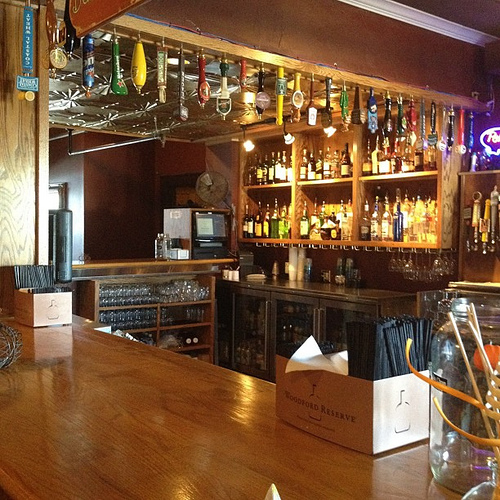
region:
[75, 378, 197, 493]
this is the counter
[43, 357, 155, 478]
the counter is wooden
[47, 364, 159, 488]
the counter is brown in color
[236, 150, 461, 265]
these are some shelves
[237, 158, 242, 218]
the shelves are wooden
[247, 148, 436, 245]
these are some bottles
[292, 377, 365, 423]
this is a box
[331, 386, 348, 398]
the box is brown in color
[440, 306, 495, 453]
this is a jar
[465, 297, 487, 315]
the jar is made of glass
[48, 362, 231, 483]
the table is clean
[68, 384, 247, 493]
the table is wooden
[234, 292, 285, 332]
this is a shelf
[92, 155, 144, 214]
this is the wall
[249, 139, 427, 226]
these are bottles of wine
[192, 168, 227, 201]
this is a fan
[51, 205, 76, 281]
this is a bottle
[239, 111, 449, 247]
Liquor bottles on shelves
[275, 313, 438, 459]
Straws and napkins in a box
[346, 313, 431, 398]
Black plastic stirring straws in a box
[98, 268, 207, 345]
Glasses on shelves under counter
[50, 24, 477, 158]
Key taps hanging from ceiling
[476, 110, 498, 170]
Neon sign on the wall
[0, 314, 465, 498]
Wooden bar top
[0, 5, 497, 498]
An empty bar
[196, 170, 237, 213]
Fan by the wall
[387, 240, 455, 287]
Wine glasses hanging upside down under shelf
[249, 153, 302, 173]
bottles of liquor on the shelf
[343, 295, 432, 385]
straws inside a box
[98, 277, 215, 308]
glasses on the shelf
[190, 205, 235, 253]
cash register on the counter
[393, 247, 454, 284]
wine glasses upside down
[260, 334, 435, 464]
box on the counter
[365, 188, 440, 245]
Spirits on the shelf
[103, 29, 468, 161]
Bottle opens on the ceiling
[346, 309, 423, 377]
straws in a box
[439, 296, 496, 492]
glass jar on the counter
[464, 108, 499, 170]
The bright neon Pabst sign barely visible.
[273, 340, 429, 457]
Brown box on the right side bar with an outline of a jug on it.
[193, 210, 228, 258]
A pos monitor over on the counter that is black.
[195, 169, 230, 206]
A round brown fan above a monitor.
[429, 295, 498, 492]
An empty glass jar by a box.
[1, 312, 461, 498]
The large area of shiny brown bar.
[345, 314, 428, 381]
The closer black straws in a box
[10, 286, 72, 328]
Further away brown box on the bar.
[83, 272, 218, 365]
A brown shelf to the left full of glass wear.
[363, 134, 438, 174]
Top shelf of glass liquor bottle next to the Pabst sign.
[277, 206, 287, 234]
bottle on the shelf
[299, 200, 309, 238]
bottle on the shelf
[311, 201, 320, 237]
bottle on the shelf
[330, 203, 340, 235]
bottle on the shelf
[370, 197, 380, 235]
bottle on the shelf